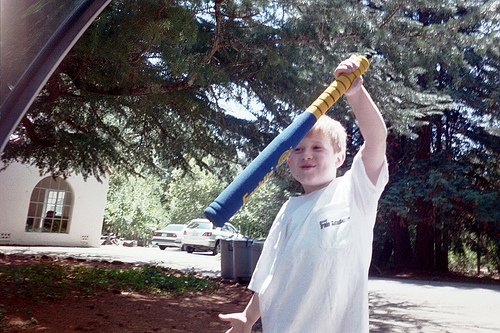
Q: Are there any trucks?
A: No, there are no trucks.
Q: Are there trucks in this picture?
A: No, there are no trucks.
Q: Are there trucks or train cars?
A: No, there are no trucks or train cars.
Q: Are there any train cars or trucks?
A: No, there are no trucks or train cars.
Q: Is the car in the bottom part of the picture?
A: Yes, the car is in the bottom of the image.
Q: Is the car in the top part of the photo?
A: No, the car is in the bottom of the image.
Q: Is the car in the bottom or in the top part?
A: The car is in the bottom of the image.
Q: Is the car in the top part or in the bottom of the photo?
A: The car is in the bottom of the image.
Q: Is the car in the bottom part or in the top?
A: The car is in the bottom of the image.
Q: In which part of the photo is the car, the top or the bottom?
A: The car is in the bottom of the image.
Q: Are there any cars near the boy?
A: Yes, there is a car near the boy.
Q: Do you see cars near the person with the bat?
A: Yes, there is a car near the boy.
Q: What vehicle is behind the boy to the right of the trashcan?
A: The vehicle is a car.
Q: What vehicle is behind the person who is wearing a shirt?
A: The vehicle is a car.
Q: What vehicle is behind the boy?
A: The vehicle is a car.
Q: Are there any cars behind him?
A: Yes, there is a car behind the boy.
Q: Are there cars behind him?
A: Yes, there is a car behind the boy.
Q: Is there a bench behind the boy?
A: No, there is a car behind the boy.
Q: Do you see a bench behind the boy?
A: No, there is a car behind the boy.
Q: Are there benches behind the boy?
A: No, there is a car behind the boy.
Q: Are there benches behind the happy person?
A: No, there is a car behind the boy.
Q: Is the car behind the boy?
A: Yes, the car is behind the boy.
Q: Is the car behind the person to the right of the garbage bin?
A: Yes, the car is behind the boy.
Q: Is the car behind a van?
A: No, the car is behind the boy.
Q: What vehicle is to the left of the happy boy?
A: The vehicle is a car.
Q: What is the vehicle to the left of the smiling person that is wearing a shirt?
A: The vehicle is a car.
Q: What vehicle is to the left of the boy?
A: The vehicle is a car.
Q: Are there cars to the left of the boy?
A: Yes, there is a car to the left of the boy.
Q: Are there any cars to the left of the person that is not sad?
A: Yes, there is a car to the left of the boy.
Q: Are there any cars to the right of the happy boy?
A: No, the car is to the left of the boy.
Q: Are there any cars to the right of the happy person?
A: No, the car is to the left of the boy.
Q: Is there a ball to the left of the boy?
A: No, there is a car to the left of the boy.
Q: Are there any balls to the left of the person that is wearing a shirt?
A: No, there is a car to the left of the boy.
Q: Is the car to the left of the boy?
A: Yes, the car is to the left of the boy.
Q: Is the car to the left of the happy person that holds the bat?
A: Yes, the car is to the left of the boy.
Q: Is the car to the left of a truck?
A: No, the car is to the left of the boy.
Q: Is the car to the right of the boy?
A: No, the car is to the left of the boy.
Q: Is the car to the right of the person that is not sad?
A: No, the car is to the left of the boy.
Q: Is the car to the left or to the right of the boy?
A: The car is to the left of the boy.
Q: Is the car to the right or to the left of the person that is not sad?
A: The car is to the left of the boy.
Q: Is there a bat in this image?
A: Yes, there is a bat.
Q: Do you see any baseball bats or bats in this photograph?
A: Yes, there is a bat.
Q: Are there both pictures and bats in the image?
A: No, there is a bat but no pictures.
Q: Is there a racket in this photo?
A: No, there are no rackets.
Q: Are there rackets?
A: No, there are no rackets.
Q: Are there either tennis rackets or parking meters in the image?
A: No, there are no tennis rackets or parking meters.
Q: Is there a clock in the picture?
A: No, there are no clocks.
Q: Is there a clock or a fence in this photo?
A: No, there are no clocks or fences.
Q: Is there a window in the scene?
A: Yes, there is a window.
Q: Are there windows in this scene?
A: Yes, there is a window.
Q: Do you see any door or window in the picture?
A: Yes, there is a window.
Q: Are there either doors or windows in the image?
A: Yes, there is a window.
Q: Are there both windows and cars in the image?
A: Yes, there are both a window and a car.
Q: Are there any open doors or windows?
A: Yes, there is an open window.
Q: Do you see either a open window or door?
A: Yes, there is an open window.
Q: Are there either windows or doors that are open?
A: Yes, the window is open.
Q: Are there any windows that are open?
A: Yes, there is an open window.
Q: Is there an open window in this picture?
A: Yes, there is an open window.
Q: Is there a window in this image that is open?
A: Yes, there is a window that is open.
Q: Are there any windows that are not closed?
A: Yes, there is a open window.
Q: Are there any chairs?
A: No, there are no chairs.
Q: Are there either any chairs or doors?
A: No, there are no chairs or doors.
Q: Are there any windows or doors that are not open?
A: No, there is a window but it is open.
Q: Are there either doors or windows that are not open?
A: No, there is a window but it is open.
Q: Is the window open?
A: Yes, the window is open.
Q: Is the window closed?
A: No, the window is open.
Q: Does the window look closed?
A: No, the window is open.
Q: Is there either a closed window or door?
A: No, there is a window but it is open.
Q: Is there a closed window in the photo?
A: No, there is a window but it is open.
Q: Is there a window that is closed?
A: No, there is a window but it is open.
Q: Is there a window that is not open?
A: No, there is a window but it is open.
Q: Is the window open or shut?
A: The window is open.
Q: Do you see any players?
A: No, there are no players.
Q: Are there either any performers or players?
A: No, there are no players or performers.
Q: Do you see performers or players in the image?
A: No, there are no players or performers.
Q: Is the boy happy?
A: Yes, the boy is happy.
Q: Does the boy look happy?
A: Yes, the boy is happy.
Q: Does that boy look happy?
A: Yes, the boy is happy.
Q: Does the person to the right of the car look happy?
A: Yes, the boy is happy.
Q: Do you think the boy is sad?
A: No, the boy is happy.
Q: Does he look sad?
A: No, the boy is happy.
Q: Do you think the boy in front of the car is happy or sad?
A: The boy is happy.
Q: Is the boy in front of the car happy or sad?
A: The boy is happy.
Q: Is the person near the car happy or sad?
A: The boy is happy.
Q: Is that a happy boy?
A: Yes, that is a happy boy.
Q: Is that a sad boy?
A: No, that is a happy boy.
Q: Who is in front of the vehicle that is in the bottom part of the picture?
A: The boy is in front of the car.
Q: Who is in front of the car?
A: The boy is in front of the car.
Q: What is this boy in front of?
A: The boy is in front of the car.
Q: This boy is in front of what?
A: The boy is in front of the car.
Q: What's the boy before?
A: The boy is in front of the car.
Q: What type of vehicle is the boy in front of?
A: The boy is in front of the car.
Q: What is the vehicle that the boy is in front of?
A: The vehicle is a car.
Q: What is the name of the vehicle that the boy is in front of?
A: The vehicle is a car.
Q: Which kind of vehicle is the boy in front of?
A: The boy is in front of the car.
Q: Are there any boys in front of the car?
A: Yes, there is a boy in front of the car.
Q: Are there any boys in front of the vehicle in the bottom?
A: Yes, there is a boy in front of the car.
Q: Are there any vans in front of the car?
A: No, there is a boy in front of the car.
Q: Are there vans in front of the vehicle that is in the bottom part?
A: No, there is a boy in front of the car.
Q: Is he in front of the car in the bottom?
A: Yes, the boy is in front of the car.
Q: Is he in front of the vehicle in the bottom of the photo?
A: Yes, the boy is in front of the car.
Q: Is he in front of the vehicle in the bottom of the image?
A: Yes, the boy is in front of the car.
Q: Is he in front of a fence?
A: No, the boy is in front of the car.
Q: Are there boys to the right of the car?
A: Yes, there is a boy to the right of the car.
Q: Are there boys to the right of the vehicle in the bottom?
A: Yes, there is a boy to the right of the car.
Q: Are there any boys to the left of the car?
A: No, the boy is to the right of the car.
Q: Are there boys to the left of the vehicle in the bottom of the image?
A: No, the boy is to the right of the car.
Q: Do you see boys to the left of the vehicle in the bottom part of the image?
A: No, the boy is to the right of the car.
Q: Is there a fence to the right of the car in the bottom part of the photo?
A: No, there is a boy to the right of the car.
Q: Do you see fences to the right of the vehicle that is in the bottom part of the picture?
A: No, there is a boy to the right of the car.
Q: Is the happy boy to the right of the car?
A: Yes, the boy is to the right of the car.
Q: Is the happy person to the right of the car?
A: Yes, the boy is to the right of the car.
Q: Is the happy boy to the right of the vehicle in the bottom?
A: Yes, the boy is to the right of the car.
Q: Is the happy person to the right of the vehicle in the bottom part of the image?
A: Yes, the boy is to the right of the car.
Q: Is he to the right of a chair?
A: No, the boy is to the right of the car.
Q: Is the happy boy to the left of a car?
A: No, the boy is to the right of a car.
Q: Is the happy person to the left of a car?
A: No, the boy is to the right of a car.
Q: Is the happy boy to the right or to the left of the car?
A: The boy is to the right of the car.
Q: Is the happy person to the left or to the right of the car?
A: The boy is to the right of the car.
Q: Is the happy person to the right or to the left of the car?
A: The boy is to the right of the car.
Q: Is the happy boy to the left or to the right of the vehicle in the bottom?
A: The boy is to the right of the car.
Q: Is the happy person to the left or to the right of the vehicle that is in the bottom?
A: The boy is to the right of the car.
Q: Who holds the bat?
A: The boy holds the bat.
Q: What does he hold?
A: The boy holds the bat.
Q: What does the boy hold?
A: The boy holds the bat.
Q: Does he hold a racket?
A: No, the boy holds the bat.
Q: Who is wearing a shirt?
A: The boy is wearing a shirt.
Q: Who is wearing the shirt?
A: The boy is wearing a shirt.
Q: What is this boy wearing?
A: The boy is wearing a shirt.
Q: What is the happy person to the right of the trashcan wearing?
A: The boy is wearing a shirt.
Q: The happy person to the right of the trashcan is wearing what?
A: The boy is wearing a shirt.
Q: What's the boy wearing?
A: The boy is wearing a shirt.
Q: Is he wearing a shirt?
A: Yes, the boy is wearing a shirt.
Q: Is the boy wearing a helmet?
A: No, the boy is wearing a shirt.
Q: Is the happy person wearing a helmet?
A: No, the boy is wearing a shirt.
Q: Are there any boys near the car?
A: Yes, there is a boy near the car.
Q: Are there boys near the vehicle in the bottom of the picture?
A: Yes, there is a boy near the car.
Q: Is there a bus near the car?
A: No, there is a boy near the car.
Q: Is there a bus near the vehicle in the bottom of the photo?
A: No, there is a boy near the car.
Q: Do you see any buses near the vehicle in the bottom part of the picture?
A: No, there is a boy near the car.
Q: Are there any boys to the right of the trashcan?
A: Yes, there is a boy to the right of the trashcan.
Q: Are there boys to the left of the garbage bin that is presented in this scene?
A: No, the boy is to the right of the garbage bin.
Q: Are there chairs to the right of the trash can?
A: No, there is a boy to the right of the trash can.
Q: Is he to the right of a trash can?
A: Yes, the boy is to the right of a trash can.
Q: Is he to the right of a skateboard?
A: No, the boy is to the right of a trash can.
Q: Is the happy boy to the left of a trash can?
A: No, the boy is to the right of a trash can.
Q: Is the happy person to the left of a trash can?
A: No, the boy is to the right of a trash can.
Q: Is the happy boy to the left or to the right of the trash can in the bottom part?
A: The boy is to the right of the trash can.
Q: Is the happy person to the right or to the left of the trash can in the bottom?
A: The boy is to the right of the trash can.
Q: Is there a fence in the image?
A: No, there are no fences.